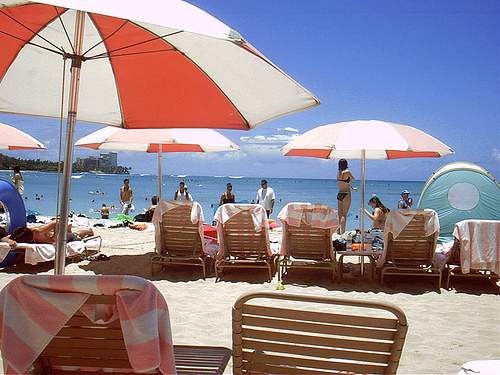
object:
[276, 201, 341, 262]
towels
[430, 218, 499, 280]
towels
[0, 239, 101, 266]
towels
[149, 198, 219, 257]
towels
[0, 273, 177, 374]
towel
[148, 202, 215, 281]
chair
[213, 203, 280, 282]
chair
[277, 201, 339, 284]
chair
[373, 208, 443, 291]
chair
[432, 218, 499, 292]
chair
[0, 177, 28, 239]
tube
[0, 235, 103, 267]
chair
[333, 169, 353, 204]
bikini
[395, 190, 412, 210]
man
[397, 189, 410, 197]
baseball cap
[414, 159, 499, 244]
beach tent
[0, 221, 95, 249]
man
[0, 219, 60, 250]
shirtless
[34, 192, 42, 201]
people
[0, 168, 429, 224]
water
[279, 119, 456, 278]
umbrella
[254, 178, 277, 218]
man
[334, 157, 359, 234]
woman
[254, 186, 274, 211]
shirt